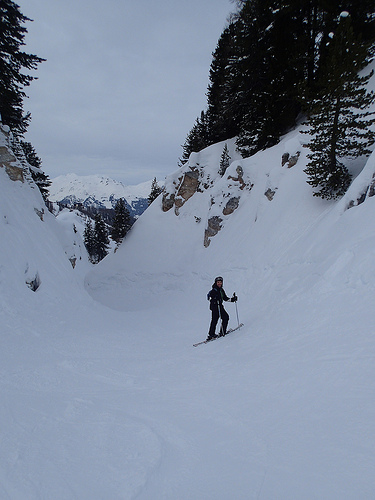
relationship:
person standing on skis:
[207, 277, 237, 339] [191, 322, 244, 348]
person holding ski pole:
[207, 277, 237, 339] [216, 301, 225, 337]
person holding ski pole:
[207, 277, 237, 339] [232, 293, 241, 328]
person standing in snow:
[207, 277, 237, 339] [0, 60, 374, 499]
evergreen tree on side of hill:
[300, 43, 375, 199] [86, 54, 374, 312]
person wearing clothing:
[207, 277, 237, 339] [206, 285, 232, 338]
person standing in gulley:
[207, 277, 237, 339] [24, 156, 257, 360]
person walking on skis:
[207, 277, 237, 339] [191, 322, 244, 348]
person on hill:
[207, 277, 237, 339] [86, 54, 374, 312]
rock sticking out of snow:
[161, 169, 199, 213] [0, 60, 374, 499]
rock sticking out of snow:
[204, 162, 244, 250] [0, 60, 374, 499]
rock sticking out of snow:
[280, 150, 300, 168] [0, 60, 374, 499]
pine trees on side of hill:
[179, 1, 374, 168] [86, 54, 374, 312]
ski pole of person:
[216, 301, 225, 337] [207, 277, 237, 339]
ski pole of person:
[232, 293, 241, 328] [207, 277, 237, 339]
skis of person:
[191, 322, 244, 348] [207, 277, 237, 339]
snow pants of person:
[209, 305, 229, 335] [207, 277, 237, 339]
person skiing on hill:
[207, 277, 237, 339] [86, 54, 374, 312]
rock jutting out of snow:
[161, 169, 199, 213] [0, 60, 374, 499]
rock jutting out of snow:
[204, 162, 244, 250] [0, 60, 374, 499]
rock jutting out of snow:
[280, 150, 300, 168] [0, 60, 374, 499]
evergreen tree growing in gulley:
[109, 198, 137, 243] [24, 156, 257, 360]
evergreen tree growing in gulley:
[93, 210, 111, 260] [24, 156, 257, 360]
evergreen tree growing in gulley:
[84, 219, 95, 254] [24, 156, 257, 360]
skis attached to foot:
[191, 322, 244, 348] [207, 334, 220, 341]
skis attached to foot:
[191, 322, 244, 348] [218, 331, 231, 337]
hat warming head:
[213, 277, 223, 284] [214, 276, 223, 290]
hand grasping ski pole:
[230, 296, 237, 304] [232, 293, 241, 328]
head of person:
[214, 276, 223, 290] [207, 277, 237, 339]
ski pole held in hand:
[232, 293, 241, 328] [230, 296, 237, 304]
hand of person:
[230, 296, 237, 304] [207, 277, 237, 339]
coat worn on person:
[207, 284, 233, 309] [207, 277, 237, 339]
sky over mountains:
[13, 1, 243, 187] [46, 172, 168, 213]